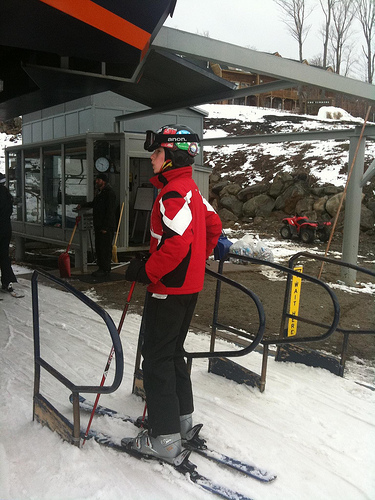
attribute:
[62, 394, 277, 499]
skis — here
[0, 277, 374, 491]
snow — white, here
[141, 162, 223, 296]
jacket — red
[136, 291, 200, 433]
pants — black, snow pants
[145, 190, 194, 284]
patches — white, black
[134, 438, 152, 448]
ski strap — grey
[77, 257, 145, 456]
ski pole — red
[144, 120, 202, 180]
head — boy's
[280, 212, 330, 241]
atv — red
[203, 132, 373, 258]
hill — rocky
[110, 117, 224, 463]
boy — waiting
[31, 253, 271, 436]
entrance — ski lift's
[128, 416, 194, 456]
feet — boy's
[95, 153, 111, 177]
clock — round, small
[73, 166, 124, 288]
man — standing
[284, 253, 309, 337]
sign — yellow, small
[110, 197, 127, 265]
broom — resting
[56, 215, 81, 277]
shovel — red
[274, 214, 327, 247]
4x4 vehicle — red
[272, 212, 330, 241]
truck — small, red, black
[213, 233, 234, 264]
trashcan — spilled over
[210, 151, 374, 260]
rocks — boulders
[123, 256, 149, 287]
gloves — black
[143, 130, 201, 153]
ski goggles — here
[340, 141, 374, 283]
pole — metal